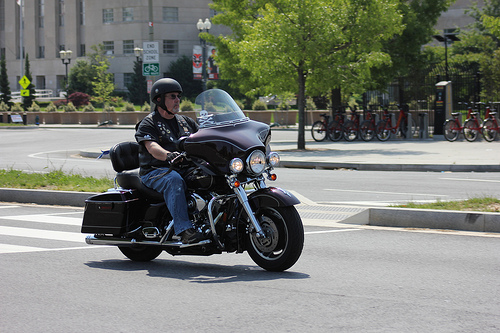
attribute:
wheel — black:
[238, 191, 305, 274]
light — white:
[245, 148, 265, 174]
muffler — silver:
[83, 234, 139, 246]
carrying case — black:
[80, 190, 144, 234]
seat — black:
[107, 140, 157, 199]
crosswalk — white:
[3, 174, 498, 254]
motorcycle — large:
[78, 87, 306, 274]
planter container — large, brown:
[57, 110, 83, 127]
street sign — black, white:
[140, 40, 160, 66]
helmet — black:
[149, 76, 182, 117]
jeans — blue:
[140, 165, 195, 233]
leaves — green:
[216, 3, 406, 97]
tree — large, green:
[206, 3, 409, 151]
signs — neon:
[18, 76, 31, 100]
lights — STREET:
[199, 17, 222, 41]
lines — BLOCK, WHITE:
[14, 216, 45, 253]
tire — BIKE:
[284, 223, 301, 241]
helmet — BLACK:
[154, 73, 182, 90]